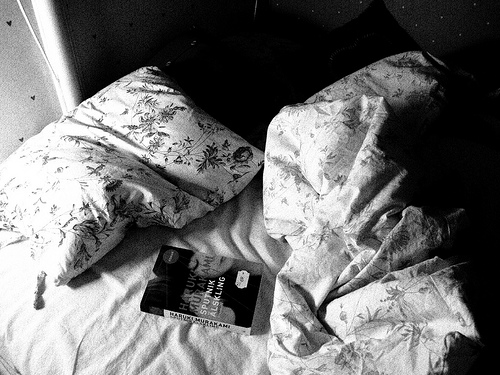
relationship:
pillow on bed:
[13, 122, 227, 189] [47, 98, 452, 373]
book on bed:
[140, 244, 265, 336] [4, 155, 493, 374]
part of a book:
[177, 248, 203, 324] [198, 260, 260, 290]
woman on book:
[154, 242, 261, 278] [139, 242, 264, 334]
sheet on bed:
[8, 306, 161, 372] [1, 50, 481, 372]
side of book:
[198, 261, 250, 321] [140, 244, 265, 336]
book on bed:
[140, 244, 265, 336] [4, 13, 492, 372]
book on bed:
[140, 244, 265, 336] [0, 127, 497, 372]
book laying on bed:
[139, 242, 264, 334] [47, 75, 467, 374]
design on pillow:
[125, 93, 184, 156] [42, 126, 204, 210]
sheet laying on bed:
[268, 48, 449, 373] [0, 62, 352, 372]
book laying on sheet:
[140, 244, 265, 336] [42, 319, 271, 373]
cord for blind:
[14, 0, 68, 100] [0, 0, 45, 155]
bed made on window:
[2, 77, 498, 371] [40, 0, 495, 205]